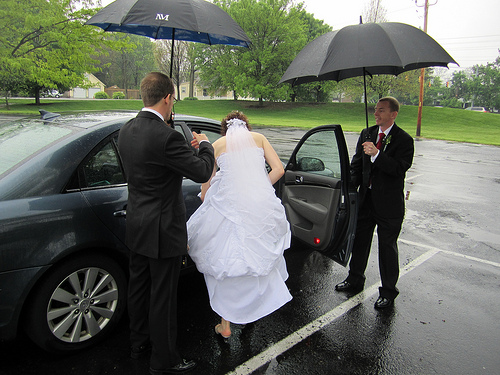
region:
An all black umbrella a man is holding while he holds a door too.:
[282, 12, 460, 157]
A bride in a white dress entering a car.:
[186, 111, 296, 338]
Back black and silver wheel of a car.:
[28, 251, 127, 349]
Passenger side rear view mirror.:
[292, 155, 327, 175]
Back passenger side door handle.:
[109, 203, 131, 217]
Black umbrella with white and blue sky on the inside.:
[83, 0, 253, 125]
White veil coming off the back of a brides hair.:
[222, 117, 261, 168]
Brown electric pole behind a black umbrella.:
[416, 0, 434, 136]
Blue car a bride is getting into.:
[0, 108, 362, 356]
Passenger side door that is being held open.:
[273, 122, 359, 269]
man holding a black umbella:
[309, 2, 450, 337]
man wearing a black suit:
[311, 78, 431, 321]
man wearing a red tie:
[331, 92, 408, 318]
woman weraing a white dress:
[206, 82, 302, 367]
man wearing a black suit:
[115, 52, 211, 372]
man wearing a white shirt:
[60, 60, 202, 372]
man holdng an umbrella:
[93, 0, 229, 276]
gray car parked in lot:
[11, 100, 112, 315]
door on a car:
[291, 107, 373, 272]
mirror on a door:
[287, 141, 335, 197]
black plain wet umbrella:
[322, 28, 430, 85]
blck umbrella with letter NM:
[100, 0, 256, 79]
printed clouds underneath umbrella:
[128, 26, 229, 47]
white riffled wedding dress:
[212, 151, 285, 300]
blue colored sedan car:
[7, 108, 365, 248]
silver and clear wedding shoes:
[217, 325, 241, 343]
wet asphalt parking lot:
[439, 158, 488, 227]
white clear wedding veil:
[217, 113, 286, 177]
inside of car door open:
[288, 133, 389, 256]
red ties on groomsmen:
[365, 131, 388, 157]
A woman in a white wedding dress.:
[165, 106, 302, 353]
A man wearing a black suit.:
[315, 80, 425, 314]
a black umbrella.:
[281, 11, 466, 103]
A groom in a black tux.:
[98, 43, 224, 373]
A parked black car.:
[0, 112, 383, 371]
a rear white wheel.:
[31, 238, 135, 370]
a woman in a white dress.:
[175, 98, 307, 355]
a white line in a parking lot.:
[232, 238, 441, 373]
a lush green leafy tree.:
[172, 0, 352, 107]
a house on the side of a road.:
[56, 68, 111, 103]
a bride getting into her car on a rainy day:
[0, 87, 359, 364]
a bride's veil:
[229, 121, 264, 236]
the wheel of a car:
[31, 252, 123, 362]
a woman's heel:
[219, 328, 234, 338]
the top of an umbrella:
[274, 13, 457, 83]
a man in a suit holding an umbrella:
[96, 0, 228, 373]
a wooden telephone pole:
[416, 0, 428, 138]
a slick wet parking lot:
[417, 151, 493, 373]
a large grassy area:
[256, 103, 353, 121]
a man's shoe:
[371, 297, 397, 308]